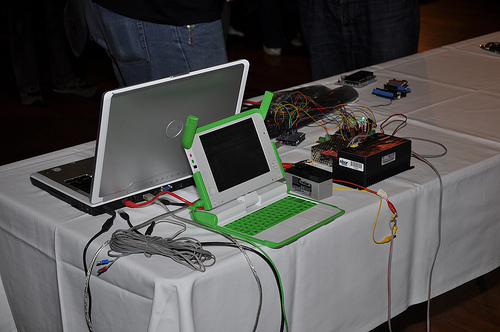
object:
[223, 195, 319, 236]
keyboard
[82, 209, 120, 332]
power cord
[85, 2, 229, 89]
jeans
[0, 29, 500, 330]
table cloth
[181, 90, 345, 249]
laptop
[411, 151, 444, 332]
wires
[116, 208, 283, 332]
cord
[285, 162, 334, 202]
battery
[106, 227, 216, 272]
bundle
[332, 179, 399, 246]
wire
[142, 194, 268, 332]
wire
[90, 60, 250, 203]
lid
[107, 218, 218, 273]
cable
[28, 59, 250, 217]
computer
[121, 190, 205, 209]
cable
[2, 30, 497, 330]
folding table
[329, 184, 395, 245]
cords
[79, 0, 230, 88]
people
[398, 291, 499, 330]
hardwood floor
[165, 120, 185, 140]
logo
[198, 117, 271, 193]
screen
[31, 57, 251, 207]
trimmings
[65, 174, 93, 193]
keys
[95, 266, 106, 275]
end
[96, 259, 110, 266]
end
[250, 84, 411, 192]
parts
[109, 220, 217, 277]
wires